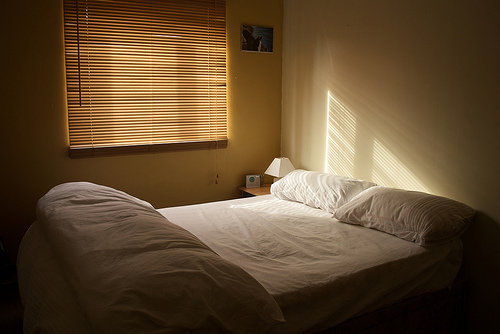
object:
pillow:
[331, 186, 478, 248]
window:
[61, 0, 230, 159]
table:
[236, 184, 272, 199]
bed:
[14, 166, 478, 334]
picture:
[237, 23, 274, 54]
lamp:
[262, 156, 295, 185]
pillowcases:
[269, 170, 380, 216]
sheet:
[19, 192, 467, 334]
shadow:
[277, 0, 500, 226]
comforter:
[35, 182, 290, 334]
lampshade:
[263, 155, 296, 179]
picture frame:
[240, 24, 274, 55]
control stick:
[75, 0, 83, 107]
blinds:
[62, 0, 227, 152]